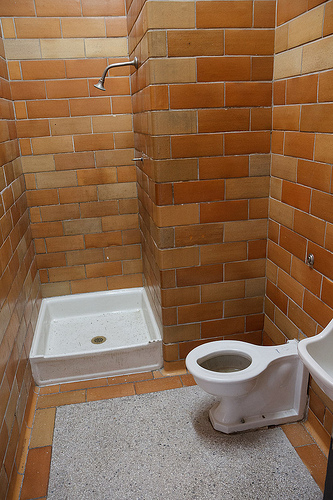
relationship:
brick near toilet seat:
[155, 158, 195, 181] [179, 334, 287, 404]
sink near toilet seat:
[294, 315, 332, 391] [179, 334, 287, 404]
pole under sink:
[320, 427, 332, 498] [294, 315, 332, 391]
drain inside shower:
[90, 332, 106, 345] [2, 51, 154, 365]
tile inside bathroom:
[68, 411, 119, 443] [5, 3, 329, 495]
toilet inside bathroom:
[179, 334, 287, 404] [5, 3, 329, 495]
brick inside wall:
[155, 158, 195, 181] [149, 45, 252, 168]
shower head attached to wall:
[90, 56, 131, 93] [127, 24, 148, 44]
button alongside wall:
[300, 250, 317, 270] [149, 45, 252, 168]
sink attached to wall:
[294, 315, 332, 391] [149, 45, 252, 168]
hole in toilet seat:
[197, 350, 252, 372] [179, 334, 287, 404]